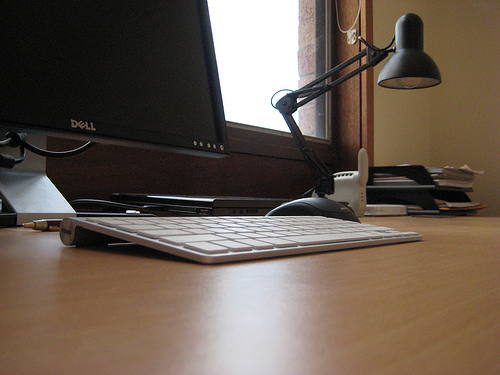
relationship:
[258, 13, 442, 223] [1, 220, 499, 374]
lamp on desk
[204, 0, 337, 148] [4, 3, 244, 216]
window behind computer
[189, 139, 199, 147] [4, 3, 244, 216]
button on computer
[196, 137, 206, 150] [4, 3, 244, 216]
button on computer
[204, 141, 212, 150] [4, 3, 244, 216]
button on computer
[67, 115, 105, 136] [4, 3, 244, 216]
dell on computer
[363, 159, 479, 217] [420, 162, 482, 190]
rack for paper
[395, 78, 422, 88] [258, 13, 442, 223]
bulb in lamp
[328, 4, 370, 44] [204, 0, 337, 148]
string for window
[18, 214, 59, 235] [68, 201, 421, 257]
pen behind keyboard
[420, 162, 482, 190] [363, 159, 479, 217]
paper in rack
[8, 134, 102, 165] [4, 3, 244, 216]
wires under computer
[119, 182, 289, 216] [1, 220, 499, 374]
laptop on desk